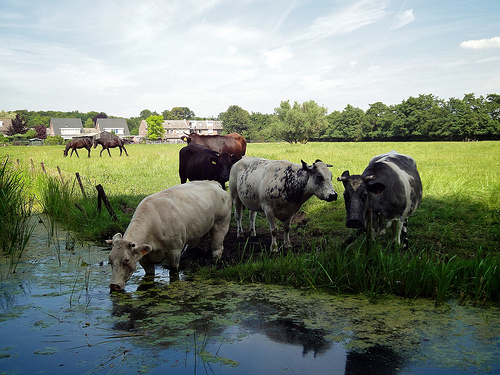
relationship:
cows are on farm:
[102, 130, 427, 291] [2, 110, 487, 282]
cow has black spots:
[225, 154, 340, 253] [233, 164, 265, 202]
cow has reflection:
[101, 176, 236, 293] [104, 279, 238, 348]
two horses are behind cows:
[59, 132, 130, 161] [102, 130, 427, 291]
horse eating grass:
[56, 132, 95, 158] [12, 156, 159, 194]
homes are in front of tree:
[47, 116, 226, 145] [145, 111, 167, 146]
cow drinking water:
[101, 176, 236, 293] [10, 292, 499, 374]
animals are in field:
[60, 130, 428, 296] [1, 144, 490, 300]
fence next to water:
[3, 153, 118, 222] [10, 292, 499, 374]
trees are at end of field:
[215, 102, 498, 140] [1, 144, 490, 300]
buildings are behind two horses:
[48, 111, 225, 149] [59, 132, 130, 161]